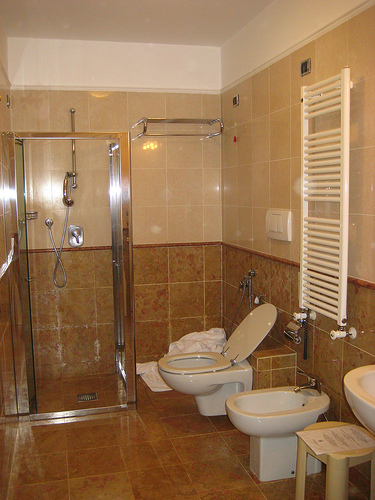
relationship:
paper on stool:
[291, 422, 374, 461] [289, 418, 372, 499]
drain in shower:
[75, 389, 98, 404] [10, 127, 144, 419]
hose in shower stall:
[42, 101, 94, 298] [10, 127, 144, 419]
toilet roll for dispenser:
[282, 319, 304, 348] [275, 307, 315, 352]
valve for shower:
[64, 221, 87, 250] [10, 127, 144, 419]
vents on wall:
[287, 64, 357, 330] [232, 35, 374, 320]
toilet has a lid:
[154, 300, 285, 420] [218, 297, 283, 366]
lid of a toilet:
[218, 297, 283, 366] [154, 300, 285, 420]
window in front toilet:
[287, 64, 357, 330] [154, 300, 285, 420]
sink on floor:
[221, 375, 324, 487] [27, 421, 254, 497]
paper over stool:
[291, 422, 374, 461] [289, 418, 372, 499]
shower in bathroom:
[10, 127, 144, 419] [2, 2, 374, 498]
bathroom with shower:
[2, 2, 374, 498] [10, 127, 144, 419]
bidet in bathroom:
[221, 375, 324, 487] [2, 2, 374, 498]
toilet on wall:
[154, 300, 285, 420] [5, 74, 293, 344]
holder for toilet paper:
[275, 307, 315, 352] [282, 319, 304, 348]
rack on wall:
[129, 112, 228, 145] [5, 74, 293, 344]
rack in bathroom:
[129, 112, 228, 145] [2, 2, 374, 498]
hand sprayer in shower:
[54, 162, 84, 214] [10, 127, 144, 419]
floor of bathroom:
[27, 421, 254, 497] [2, 2, 374, 498]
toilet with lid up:
[154, 300, 285, 420] [218, 297, 283, 366]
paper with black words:
[291, 422, 374, 461] [313, 426, 363, 448]